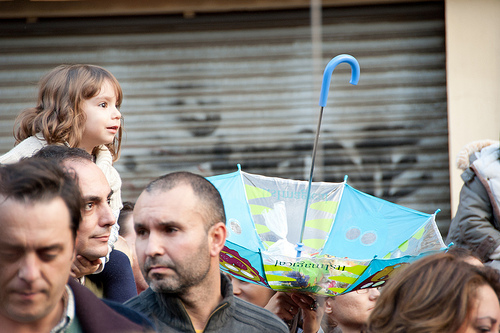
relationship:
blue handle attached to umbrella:
[318, 52, 361, 108] [146, 53, 457, 301]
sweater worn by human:
[126, 278, 288, 331] [90, 167, 290, 332]